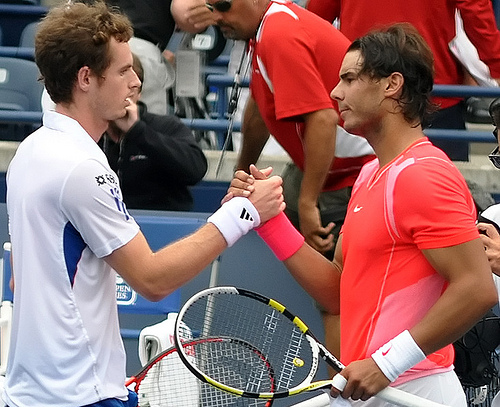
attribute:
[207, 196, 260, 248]
wrist band — white, black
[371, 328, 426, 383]
wrist band — white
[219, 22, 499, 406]
man — athletic, young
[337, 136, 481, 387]
shirt — red, pink, short sleeved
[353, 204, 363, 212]
nike logo — white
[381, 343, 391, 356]
nike logo — pink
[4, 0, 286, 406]
man — athletic, young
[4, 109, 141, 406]
shirt — white, blue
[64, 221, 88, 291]
patch — blue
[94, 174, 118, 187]
lettering — black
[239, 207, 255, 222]
logo — black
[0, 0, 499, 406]
men — tennis players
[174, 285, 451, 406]
tennis racket — yellow,black, white, yellow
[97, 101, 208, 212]
jacket — black, long sleeved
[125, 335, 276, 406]
tennis racket — red, black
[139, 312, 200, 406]
towel — white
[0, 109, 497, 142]
pole — blue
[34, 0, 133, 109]
hair — brown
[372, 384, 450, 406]
grip — white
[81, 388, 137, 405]
shorts — blue